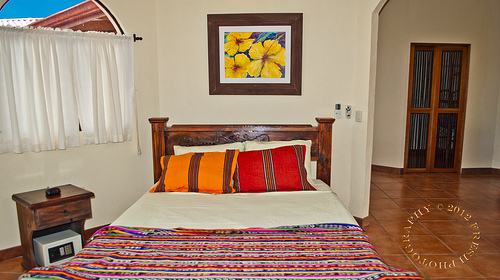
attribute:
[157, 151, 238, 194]
pillow — orange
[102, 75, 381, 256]
headboard — wooden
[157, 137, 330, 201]
pillows — colorful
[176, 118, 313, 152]
pillows — colorful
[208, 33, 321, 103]
flower — yellow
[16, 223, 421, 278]
blanket — colorful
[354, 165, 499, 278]
tile floor — brown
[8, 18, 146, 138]
curtains — white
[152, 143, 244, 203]
pillow — orange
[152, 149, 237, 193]
pillow — orange, red, white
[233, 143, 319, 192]
pillow — orange, red, white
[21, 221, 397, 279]
blanket — multicolored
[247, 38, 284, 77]
flower — yellow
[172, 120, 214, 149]
headboard — wooden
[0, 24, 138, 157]
curtain — white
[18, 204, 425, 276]
bed spread — multi-colored